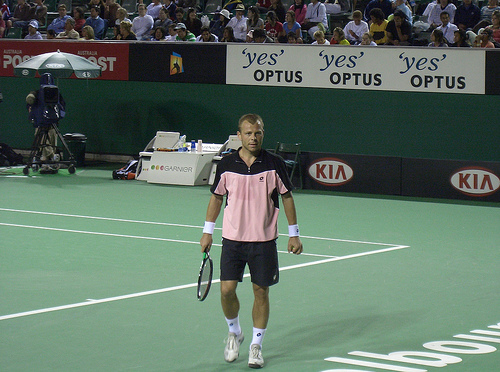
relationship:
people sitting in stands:
[5, 1, 495, 51] [11, 1, 497, 202]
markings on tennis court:
[3, 203, 407, 319] [1, 162, 495, 370]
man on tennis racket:
[196, 115, 303, 364] [192, 248, 212, 298]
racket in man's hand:
[192, 244, 216, 303] [200, 233, 212, 251]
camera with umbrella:
[23, 80, 119, 163] [24, 43, 144, 98]